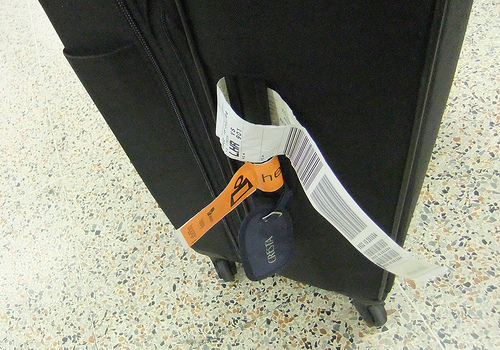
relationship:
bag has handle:
[38, 1, 473, 327] [224, 15, 284, 192]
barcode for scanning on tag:
[281, 125, 323, 190] [240, 203, 295, 282]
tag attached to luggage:
[240, 203, 295, 282] [46, 0, 398, 320]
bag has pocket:
[67, 14, 466, 307] [61, 40, 147, 75]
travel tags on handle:
[173, 75, 447, 287] [215, 69, 304, 211]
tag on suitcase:
[240, 203, 295, 282] [114, 24, 415, 276]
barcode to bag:
[281, 125, 323, 190] [38, 1, 473, 327]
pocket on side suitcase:
[59, 37, 164, 123] [36, 0, 478, 326]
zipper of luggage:
[167, 5, 238, 266] [65, 23, 467, 337]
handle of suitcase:
[199, 17, 338, 243] [97, 17, 421, 304]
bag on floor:
[38, 1, 473, 327] [3, 0, 177, 348]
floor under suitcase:
[45, 254, 190, 331] [36, 0, 478, 326]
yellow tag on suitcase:
[157, 157, 280, 249] [36, 0, 478, 326]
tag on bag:
[240, 203, 295, 282] [38, 1, 473, 327]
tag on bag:
[175, 153, 287, 248] [38, 1, 473, 327]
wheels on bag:
[203, 255, 395, 325] [38, 1, 473, 327]